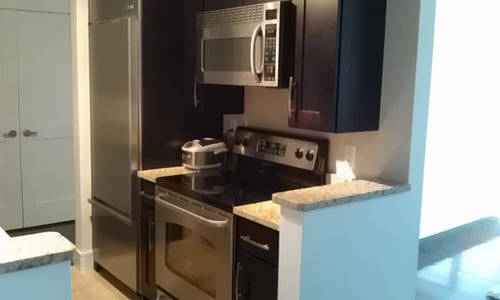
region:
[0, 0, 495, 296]
a modern kitchen with a stove and refrigerator and microwave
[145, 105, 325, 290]
a modern stove in a modern kitchen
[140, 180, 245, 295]
the oven door on a modern stove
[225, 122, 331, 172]
the dials on a stove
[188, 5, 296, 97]
a modern microwave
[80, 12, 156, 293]
a modern refrigerator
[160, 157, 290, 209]
the top of a modern stove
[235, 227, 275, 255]
the handle on a kitchen drawer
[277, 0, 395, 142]
a kitchen cabinet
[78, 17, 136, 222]
the refrigerator door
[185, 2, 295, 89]
Gray metal microwave with large handle and black buttons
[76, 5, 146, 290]
Tall stainless steel fridge with freezer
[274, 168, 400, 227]
Marble counter top over white surface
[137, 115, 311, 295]
Stainless steel oven with black top and black trim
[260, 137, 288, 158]
Display of stainless steel oven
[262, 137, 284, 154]
Green lettering on oven display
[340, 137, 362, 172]
Unused white outlet on a white wall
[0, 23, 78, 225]
Closed double white doors with gray metal door knobs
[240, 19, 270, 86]
Gray microwave metal handle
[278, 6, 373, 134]
Black cabinet with protruding metal handle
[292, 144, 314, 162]
Two black knobs on the stove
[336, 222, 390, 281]
The wall by the stove is white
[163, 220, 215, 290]
A window on the oven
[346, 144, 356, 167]
A white outlet by the stove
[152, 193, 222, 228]
The handle of the oven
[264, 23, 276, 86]
Buttons on the microwave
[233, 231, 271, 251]
A handle on a kitchen drawer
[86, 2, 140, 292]
A silver refridgerator by the stove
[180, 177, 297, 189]
The stove top is black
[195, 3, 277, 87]
A microwave above the stove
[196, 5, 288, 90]
a brush aluminum microwave and hood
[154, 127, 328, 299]
a black and brushed aluminum oven and stove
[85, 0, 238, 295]
a brushed aluminum refrigerator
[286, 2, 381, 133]
a black overhead cabinet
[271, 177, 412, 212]
a small granite shelf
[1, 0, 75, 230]
a pair of white doors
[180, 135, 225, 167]
a toaster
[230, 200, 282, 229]
a granite countertop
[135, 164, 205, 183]
a granite countertop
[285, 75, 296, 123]
a cabinet pull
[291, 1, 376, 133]
black cupboard on the wall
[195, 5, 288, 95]
microwave oven built into wall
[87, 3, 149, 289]
fridge up against the wall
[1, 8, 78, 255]
closet doors in the hall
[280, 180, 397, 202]
marble counter top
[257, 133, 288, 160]
clock on the stove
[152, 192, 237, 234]
silver handle on the stove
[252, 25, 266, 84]
silver handle on the microwave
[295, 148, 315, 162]
black knobs on the stove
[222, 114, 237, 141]
outlet for elecricity